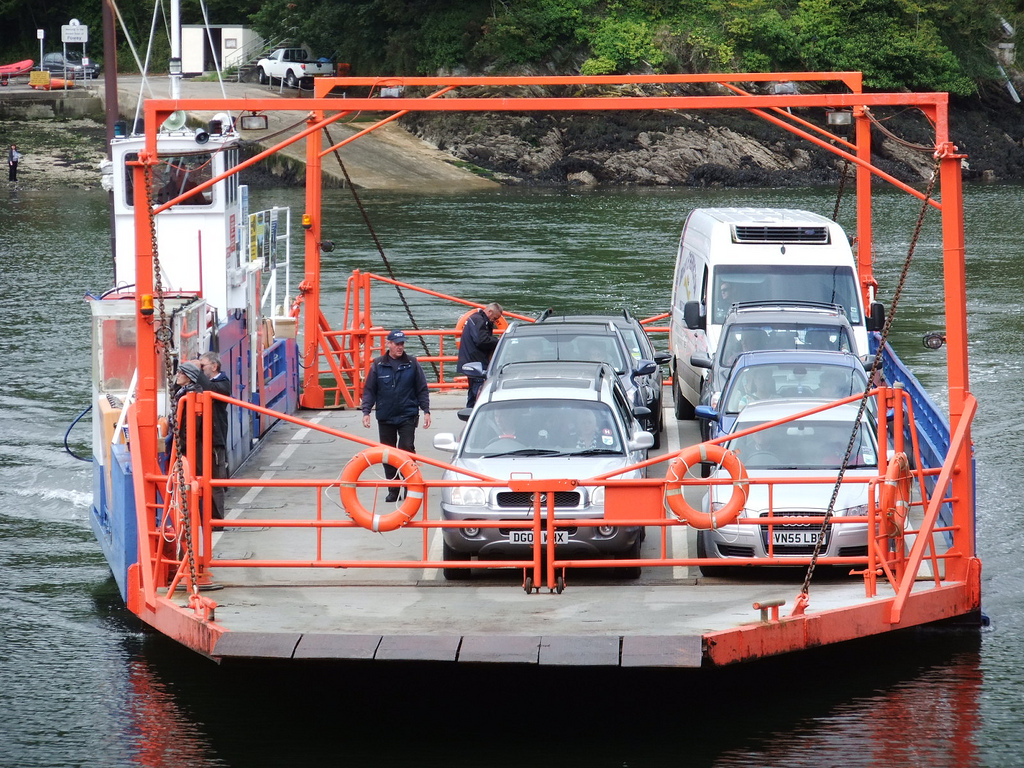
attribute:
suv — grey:
[706, 286, 862, 380]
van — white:
[637, 173, 890, 398]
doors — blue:
[218, 308, 266, 471]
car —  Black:
[40, 45, 99, 78]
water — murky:
[49, 620, 335, 727]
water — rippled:
[15, 402, 214, 660]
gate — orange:
[138, 346, 988, 632]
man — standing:
[347, 340, 508, 520]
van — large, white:
[650, 193, 886, 427]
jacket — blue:
[359, 356, 433, 423]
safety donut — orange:
[330, 438, 434, 534]